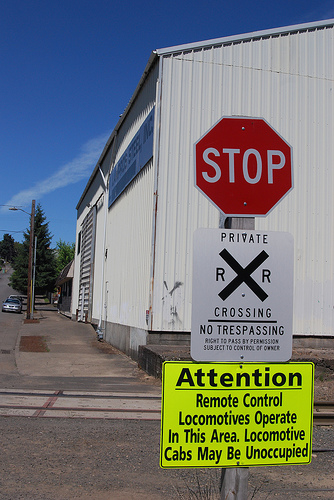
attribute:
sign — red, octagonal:
[191, 112, 296, 221]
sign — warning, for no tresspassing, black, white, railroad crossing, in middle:
[193, 228, 294, 364]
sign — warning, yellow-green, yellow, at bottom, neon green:
[159, 362, 310, 465]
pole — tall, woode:
[29, 201, 35, 321]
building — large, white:
[77, 18, 330, 339]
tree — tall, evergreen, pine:
[12, 206, 59, 295]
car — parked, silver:
[1, 299, 21, 315]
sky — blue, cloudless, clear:
[8, 0, 140, 188]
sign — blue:
[105, 110, 161, 208]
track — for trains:
[2, 386, 330, 423]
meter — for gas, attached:
[92, 324, 109, 341]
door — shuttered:
[78, 218, 91, 321]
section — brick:
[18, 336, 45, 351]